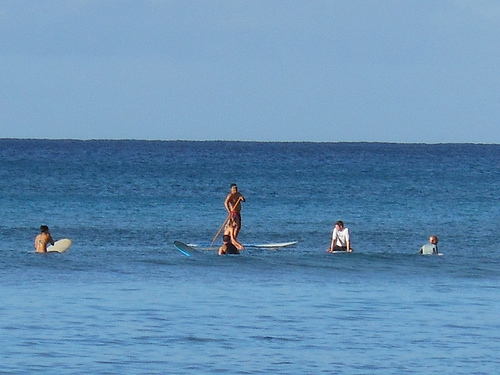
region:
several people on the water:
[10, 173, 455, 270]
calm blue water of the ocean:
[203, 268, 359, 344]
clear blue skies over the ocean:
[152, 20, 337, 111]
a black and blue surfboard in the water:
[173, 235, 203, 258]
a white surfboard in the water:
[46, 227, 76, 256]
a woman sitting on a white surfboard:
[34, 222, 62, 268]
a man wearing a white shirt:
[321, 213, 361, 253]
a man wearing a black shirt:
[215, 230, 248, 258]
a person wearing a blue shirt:
[411, 233, 452, 258]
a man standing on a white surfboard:
[194, 185, 296, 247]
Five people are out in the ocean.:
[30, 177, 445, 262]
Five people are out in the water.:
[29, 177, 445, 259]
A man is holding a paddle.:
[207, 180, 253, 250]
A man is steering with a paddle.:
[203, 180, 248, 252]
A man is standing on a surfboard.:
[218, 180, 247, 252]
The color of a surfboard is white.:
[185, 234, 299, 250]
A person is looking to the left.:
[325, 216, 352, 254]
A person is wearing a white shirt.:
[329, 217, 351, 252]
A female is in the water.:
[30, 223, 72, 256]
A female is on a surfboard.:
[30, 222, 72, 259]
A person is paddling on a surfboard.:
[189, 181, 298, 267]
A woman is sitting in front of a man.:
[216, 215, 244, 244]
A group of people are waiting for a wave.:
[37, 215, 452, 280]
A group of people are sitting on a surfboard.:
[18, 217, 468, 274]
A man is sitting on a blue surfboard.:
[171, 237, 258, 278]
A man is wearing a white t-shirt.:
[328, 210, 348, 268]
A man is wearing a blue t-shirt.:
[411, 225, 463, 285]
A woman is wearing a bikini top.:
[22, 203, 70, 265]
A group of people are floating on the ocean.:
[27, 170, 474, 302]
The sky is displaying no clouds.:
[41, 28, 404, 153]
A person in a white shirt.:
[332, 216, 364, 257]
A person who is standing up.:
[223, 178, 248, 245]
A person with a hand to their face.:
[32, 218, 52, 261]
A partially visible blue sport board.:
[168, 232, 198, 259]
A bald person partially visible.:
[418, 228, 442, 255]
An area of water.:
[11, 141, 498, 373]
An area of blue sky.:
[3, 2, 498, 144]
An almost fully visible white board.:
[188, 235, 303, 250]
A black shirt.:
[221, 241, 241, 253]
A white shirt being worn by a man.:
[331, 220, 348, 250]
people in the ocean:
[19, 166, 456, 282]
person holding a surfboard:
[28, 220, 73, 262]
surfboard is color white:
[48, 232, 75, 256]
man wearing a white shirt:
[322, 216, 358, 261]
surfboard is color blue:
[170, 234, 201, 260]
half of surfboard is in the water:
[170, 234, 214, 265]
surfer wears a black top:
[211, 225, 243, 259]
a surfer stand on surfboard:
[217, 182, 299, 253]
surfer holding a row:
[210, 175, 250, 248]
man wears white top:
[325, 218, 357, 257]